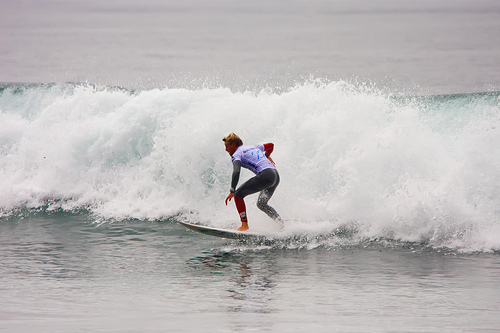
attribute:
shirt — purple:
[233, 143, 276, 174]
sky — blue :
[1, 0, 488, 104]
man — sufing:
[189, 107, 341, 223]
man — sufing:
[193, 126, 310, 243]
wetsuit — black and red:
[189, 139, 320, 237]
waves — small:
[195, 240, 351, 273]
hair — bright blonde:
[220, 132, 243, 146]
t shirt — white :
[228, 144, 276, 176]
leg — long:
[230, 170, 270, 230]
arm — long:
[227, 157, 242, 197]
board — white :
[177, 219, 272, 239]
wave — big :
[4, 77, 496, 251]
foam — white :
[4, 83, 495, 256]